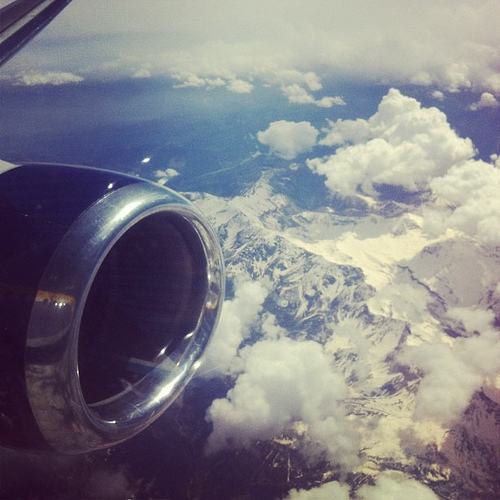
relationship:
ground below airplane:
[227, 106, 499, 499] [1, 0, 225, 454]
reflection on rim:
[122, 322, 225, 412] [146, 191, 223, 432]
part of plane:
[0, 1, 76, 92] [11, 11, 298, 381]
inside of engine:
[74, 206, 210, 403] [2, 163, 224, 457]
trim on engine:
[19, 168, 227, 473] [3, 149, 230, 490]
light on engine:
[77, 178, 177, 226] [2, 163, 224, 457]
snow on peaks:
[344, 239, 372, 264] [348, 260, 411, 348]